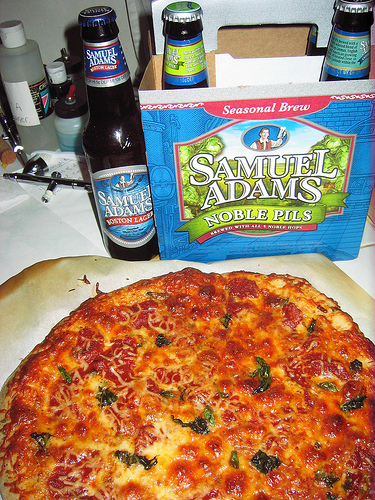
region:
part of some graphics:
[230, 152, 295, 203]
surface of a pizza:
[157, 378, 244, 460]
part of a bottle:
[100, 192, 145, 235]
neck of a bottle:
[94, 85, 125, 105]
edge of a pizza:
[0, 364, 19, 395]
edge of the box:
[151, 208, 161, 228]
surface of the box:
[245, 0, 285, 32]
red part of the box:
[254, 97, 286, 123]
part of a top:
[2, 27, 32, 49]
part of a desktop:
[28, 220, 62, 233]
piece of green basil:
[103, 446, 168, 472]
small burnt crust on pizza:
[225, 475, 253, 498]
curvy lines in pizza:
[97, 339, 154, 382]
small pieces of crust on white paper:
[63, 272, 102, 287]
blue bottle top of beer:
[51, 1, 133, 26]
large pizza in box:
[61, 268, 370, 465]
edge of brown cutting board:
[5, 242, 86, 285]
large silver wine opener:
[5, 160, 123, 218]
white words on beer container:
[190, 144, 342, 223]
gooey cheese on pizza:
[148, 432, 190, 455]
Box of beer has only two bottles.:
[133, 1, 374, 265]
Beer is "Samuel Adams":
[169, 111, 358, 239]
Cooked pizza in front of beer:
[1, 255, 370, 497]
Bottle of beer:
[62, 0, 161, 265]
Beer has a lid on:
[70, 1, 160, 267]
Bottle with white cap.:
[3, 19, 61, 156]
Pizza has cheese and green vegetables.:
[1, 260, 371, 498]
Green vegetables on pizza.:
[174, 349, 285, 477]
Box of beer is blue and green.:
[137, 68, 372, 268]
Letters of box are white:
[183, 144, 345, 229]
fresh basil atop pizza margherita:
[243, 353, 274, 400]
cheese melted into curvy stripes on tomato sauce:
[99, 305, 213, 415]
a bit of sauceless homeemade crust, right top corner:
[226, 262, 362, 342]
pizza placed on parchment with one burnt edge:
[0, 243, 374, 498]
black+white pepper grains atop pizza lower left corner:
[2, 396, 56, 497]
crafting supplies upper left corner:
[0, 12, 95, 162]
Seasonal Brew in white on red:
[220, 103, 312, 115]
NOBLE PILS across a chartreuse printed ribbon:
[173, 188, 356, 249]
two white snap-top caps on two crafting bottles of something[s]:
[0, 13, 69, 89]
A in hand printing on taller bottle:
[11, 97, 26, 115]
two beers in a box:
[157, 1, 373, 92]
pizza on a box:
[2, 264, 356, 498]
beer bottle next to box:
[76, 4, 158, 262]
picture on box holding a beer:
[231, 118, 298, 156]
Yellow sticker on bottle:
[162, 36, 204, 79]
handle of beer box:
[150, 1, 353, 60]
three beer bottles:
[61, 1, 365, 268]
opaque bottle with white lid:
[1, 18, 66, 169]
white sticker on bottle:
[2, 74, 47, 141]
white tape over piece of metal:
[33, 185, 61, 212]